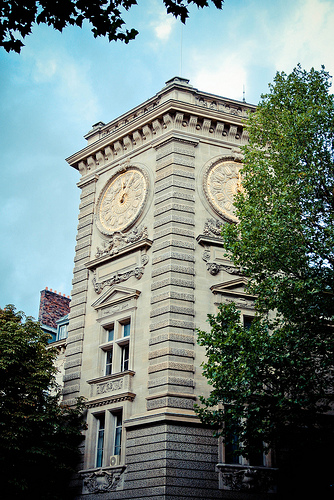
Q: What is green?
A: Tree.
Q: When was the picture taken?
A: Daytime.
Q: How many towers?
A: One.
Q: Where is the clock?
A: Middle of the tower.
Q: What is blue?
A: Sky.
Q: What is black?
A: Shadows under the trees.